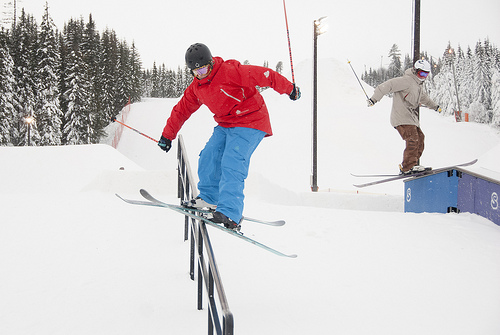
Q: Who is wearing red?
A: Skier on the left.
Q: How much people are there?
A: Two.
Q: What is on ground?
A: Snow.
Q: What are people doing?
A: Skiing.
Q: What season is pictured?
A: Winter.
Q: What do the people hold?
A: Ski poles.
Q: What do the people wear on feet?
A: Snow skis.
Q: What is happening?
A: Snow skiing.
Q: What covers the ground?
A: Snow.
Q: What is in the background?
A: Tall evergreen trees.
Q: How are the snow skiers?
A: In the air or a rail.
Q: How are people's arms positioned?
A: Outstretched.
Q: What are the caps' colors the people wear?
A: White and black caps.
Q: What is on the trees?
A: Snow.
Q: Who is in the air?
A: A skier.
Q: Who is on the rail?
A: A man.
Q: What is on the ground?
A: Snow.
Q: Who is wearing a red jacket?
A: The skier.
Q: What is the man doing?
A: Tricks.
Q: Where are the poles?
A: In the skiers hands.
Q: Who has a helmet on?
A: The skiers.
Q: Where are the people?
A: On a mountain.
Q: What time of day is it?
A: Day time.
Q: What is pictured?
A: Skier.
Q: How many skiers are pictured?
A: 2.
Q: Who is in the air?
A: Man.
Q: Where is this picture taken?
A: Ski slope.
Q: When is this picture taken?
A: While skiing.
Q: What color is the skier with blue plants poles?
A: Red.